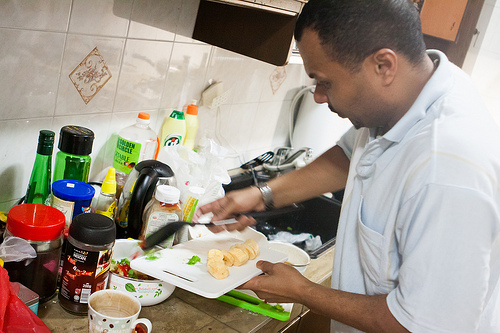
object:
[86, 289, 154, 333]
coffee mug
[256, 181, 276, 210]
watch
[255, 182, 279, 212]
wrist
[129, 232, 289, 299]
rectangular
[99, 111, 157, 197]
bottle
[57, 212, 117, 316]
coffee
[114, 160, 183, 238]
pot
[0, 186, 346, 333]
counter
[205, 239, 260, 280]
food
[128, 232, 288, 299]
plate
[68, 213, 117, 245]
lid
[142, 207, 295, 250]
ladle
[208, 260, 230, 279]
banana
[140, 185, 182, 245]
ketchup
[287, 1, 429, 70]
hair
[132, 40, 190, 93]
wall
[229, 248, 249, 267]
block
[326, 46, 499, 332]
shirt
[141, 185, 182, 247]
bottle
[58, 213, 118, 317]
jar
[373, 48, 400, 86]
ear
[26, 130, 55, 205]
green bottle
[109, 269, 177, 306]
bowl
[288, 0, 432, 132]
head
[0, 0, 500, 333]
kitchen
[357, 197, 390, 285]
pocket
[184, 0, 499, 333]
man